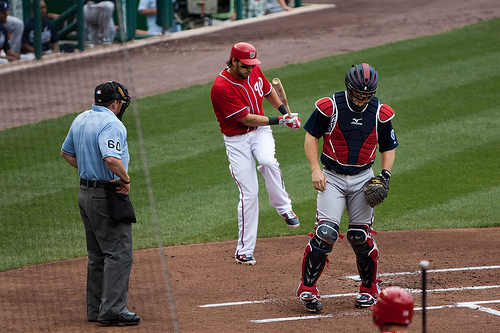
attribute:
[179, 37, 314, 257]
person — head 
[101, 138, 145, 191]
arm — person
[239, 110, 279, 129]
arm — person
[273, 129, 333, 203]
arm — person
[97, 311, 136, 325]
shoe — feet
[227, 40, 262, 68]
hat — head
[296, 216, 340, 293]
leg pad — red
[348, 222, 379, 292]
leg pad — black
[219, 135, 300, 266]
legs — person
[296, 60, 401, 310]
person — legs 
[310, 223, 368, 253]
kneepads —  knees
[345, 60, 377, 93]
helmet — black, red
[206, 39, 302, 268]
player — white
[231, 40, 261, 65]
cap — red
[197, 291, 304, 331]
lines — white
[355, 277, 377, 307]
sneakers — black, red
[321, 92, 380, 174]
vest — red, black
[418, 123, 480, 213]
pattern — striped 